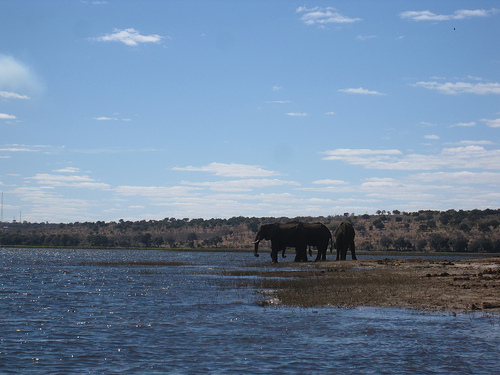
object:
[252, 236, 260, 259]
nose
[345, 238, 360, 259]
leg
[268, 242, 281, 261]
leg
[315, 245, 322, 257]
leg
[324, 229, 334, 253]
tail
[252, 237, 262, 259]
trunk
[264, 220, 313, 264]
body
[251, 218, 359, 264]
elephant herd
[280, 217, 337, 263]
elephant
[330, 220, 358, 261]
elephant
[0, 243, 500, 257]
shore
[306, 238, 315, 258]
tail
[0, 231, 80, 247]
bushes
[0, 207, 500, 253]
hillside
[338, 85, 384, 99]
cloud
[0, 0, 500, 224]
sky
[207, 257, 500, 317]
bank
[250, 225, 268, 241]
face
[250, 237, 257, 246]
tusk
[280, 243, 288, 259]
trunk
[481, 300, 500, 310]
clumps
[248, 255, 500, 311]
sand bar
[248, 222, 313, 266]
animal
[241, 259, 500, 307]
dirt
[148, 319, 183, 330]
ripples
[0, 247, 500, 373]
water